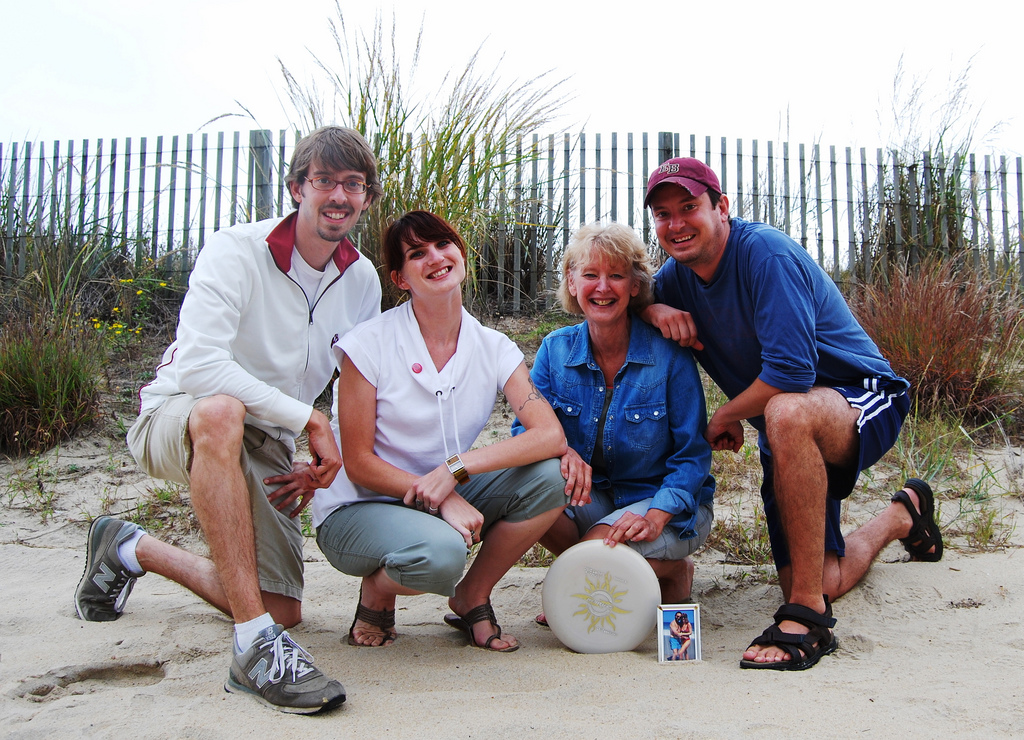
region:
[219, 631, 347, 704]
Silver N on the side of brown shoe.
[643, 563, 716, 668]
Small blue and white picture on the ground.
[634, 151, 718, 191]
Red hat on top of man's head.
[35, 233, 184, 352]
Yellow flowers in the bunch of trees.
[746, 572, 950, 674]
Black sandals on the man's feet.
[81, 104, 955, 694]
Group of people kneeling down in the dirt.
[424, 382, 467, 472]
Two strings hanging down from the woman's shirt.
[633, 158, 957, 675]
Man wearing a burgundy hat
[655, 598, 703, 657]
Picture frame next to a frisbee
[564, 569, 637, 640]
Sun graphic printed onto the frisbee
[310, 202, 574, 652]
Woman wearing a white sweater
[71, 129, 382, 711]
Man wearing a red and white sweater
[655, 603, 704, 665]
Picture frame standing on the sand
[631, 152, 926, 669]
Man in hat is kneeling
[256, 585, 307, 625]
Knee is on the ground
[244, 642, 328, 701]
foot on the person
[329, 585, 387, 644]
foot on the person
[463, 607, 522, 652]
foot on the person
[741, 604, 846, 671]
foot on the person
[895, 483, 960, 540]
foot on the person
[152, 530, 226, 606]
leg of the person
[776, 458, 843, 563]
leg of the person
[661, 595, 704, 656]
Small photo on the ground.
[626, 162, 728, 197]
Red hat on top of the man's head.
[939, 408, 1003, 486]
Bunch of grass in the sand.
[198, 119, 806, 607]
Group of people kneeling in the sand.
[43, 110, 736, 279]
Thin fence behind the sand.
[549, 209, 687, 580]
a perosn on the beach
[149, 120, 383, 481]
a white male wearing a jacket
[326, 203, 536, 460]
a white female wearing a jacket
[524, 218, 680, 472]
a white female wearing a denim jacket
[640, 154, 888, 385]
a white male wearing a blue shirt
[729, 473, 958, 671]
a pair of black sandals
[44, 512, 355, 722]
a grey pair of rubber shoes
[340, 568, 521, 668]
a pair of women's sandals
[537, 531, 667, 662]
a white Frisbee with a sun on the middle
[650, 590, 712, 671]
a small picture frame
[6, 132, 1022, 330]
a long wooden fence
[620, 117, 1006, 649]
a person on the baech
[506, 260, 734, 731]
a person on the baech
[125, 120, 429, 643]
a person on the baech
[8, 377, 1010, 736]
Light brown sand on the ground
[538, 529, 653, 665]
A round frisbee with a sun design on it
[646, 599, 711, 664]
A picture in a frame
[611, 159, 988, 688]
A man wearing dark sandals.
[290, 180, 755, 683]
Two women squatting down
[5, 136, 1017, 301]
A brown wooden fence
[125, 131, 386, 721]
A man wearing glasses.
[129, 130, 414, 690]
A man with dark brown hair.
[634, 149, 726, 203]
A burgundy ball cap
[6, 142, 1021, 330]
a long fence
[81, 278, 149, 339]
yellow flowers in front of the fence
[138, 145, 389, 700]
a man in a white jacket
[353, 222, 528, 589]
a woman in a white jacket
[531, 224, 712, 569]
a woman in a blue shirt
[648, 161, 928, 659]
a man with a red cap on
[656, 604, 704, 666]
a picture on the sand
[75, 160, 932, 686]
four people posing for a picture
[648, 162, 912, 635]
a man in a blue shirt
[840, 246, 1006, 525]
weeds in front of the fence